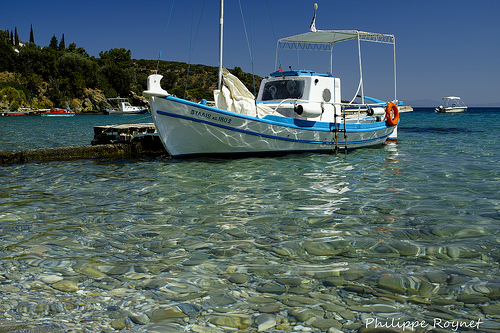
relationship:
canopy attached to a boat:
[274, 14, 394, 106] [136, 70, 408, 168]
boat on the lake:
[135, 21, 405, 157] [20, 110, 470, 320]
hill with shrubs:
[13, 31, 225, 109] [23, 78, 101, 103]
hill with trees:
[13, 31, 225, 109] [35, 37, 135, 82]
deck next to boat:
[90, 119, 148, 144] [135, 21, 405, 157]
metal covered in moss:
[8, 143, 129, 156] [3, 147, 145, 161]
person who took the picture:
[364, 305, 483, 328] [9, 17, 485, 319]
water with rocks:
[18, 130, 451, 330] [24, 155, 461, 316]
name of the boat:
[188, 104, 236, 127] [135, 21, 405, 157]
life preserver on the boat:
[385, 101, 400, 126] [135, 21, 405, 157]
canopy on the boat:
[274, 14, 394, 106] [135, 21, 405, 157]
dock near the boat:
[88, 119, 151, 149] [135, 21, 405, 157]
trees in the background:
[4, 21, 82, 47] [14, 22, 262, 113]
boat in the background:
[40, 105, 76, 117] [9, 45, 119, 131]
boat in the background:
[434, 96, 469, 114] [405, 58, 485, 134]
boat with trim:
[135, 0, 405, 157] [162, 96, 402, 133]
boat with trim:
[135, 0, 405, 157] [273, 67, 334, 78]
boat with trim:
[135, 0, 405, 157] [159, 108, 390, 148]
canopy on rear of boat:
[274, 14, 394, 106] [135, 21, 405, 157]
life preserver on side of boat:
[383, 101, 400, 123] [135, 0, 405, 157]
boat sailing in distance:
[433, 91, 470, 122] [413, 62, 479, 118]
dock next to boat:
[91, 122, 158, 149] [135, 0, 405, 157]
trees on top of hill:
[47, 27, 67, 52] [10, 56, 128, 106]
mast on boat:
[209, 9, 227, 103] [135, 21, 405, 157]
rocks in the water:
[142, 285, 193, 322] [21, 107, 464, 313]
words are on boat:
[173, 104, 243, 133] [140, 0, 410, 165]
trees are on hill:
[85, 44, 136, 99] [0, 56, 275, 127]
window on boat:
[318, 83, 338, 101] [140, 0, 410, 165]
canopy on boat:
[274, 14, 394, 106] [140, 0, 410, 165]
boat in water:
[0, 99, 80, 119] [0, 110, 496, 326]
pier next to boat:
[2, 134, 166, 172] [140, 0, 410, 165]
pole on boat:
[210, 0, 235, 105] [140, 0, 410, 165]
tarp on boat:
[218, 66, 264, 128] [140, 0, 410, 165]